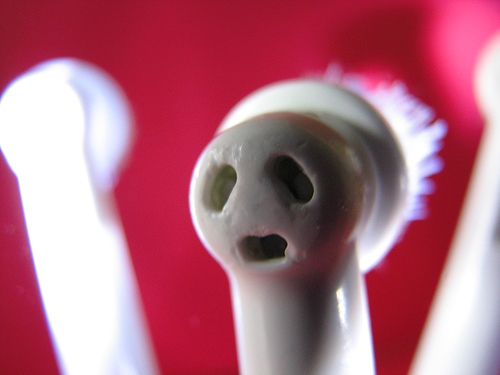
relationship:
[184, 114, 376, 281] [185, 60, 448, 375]
back end of brush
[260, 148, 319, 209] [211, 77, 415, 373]
hole on toothbrush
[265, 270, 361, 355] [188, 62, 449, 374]
shadow on toothbrush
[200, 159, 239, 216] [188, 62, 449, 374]
hole on toothbrush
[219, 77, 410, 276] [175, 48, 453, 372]
rim of brush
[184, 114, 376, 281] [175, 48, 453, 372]
back end of brush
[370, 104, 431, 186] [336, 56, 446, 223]
light hitting bristles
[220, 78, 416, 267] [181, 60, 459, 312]
front of brush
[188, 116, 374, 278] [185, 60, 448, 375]
back end of brush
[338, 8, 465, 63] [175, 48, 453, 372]
shadows on brush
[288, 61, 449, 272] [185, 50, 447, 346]
bristles on brush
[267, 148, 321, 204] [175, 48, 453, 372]
hole in brush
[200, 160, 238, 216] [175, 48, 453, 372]
hole in brush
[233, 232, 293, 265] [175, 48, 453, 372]
hole in brush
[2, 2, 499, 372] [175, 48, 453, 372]
red cloth behind brush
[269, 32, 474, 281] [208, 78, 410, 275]
bristles on head